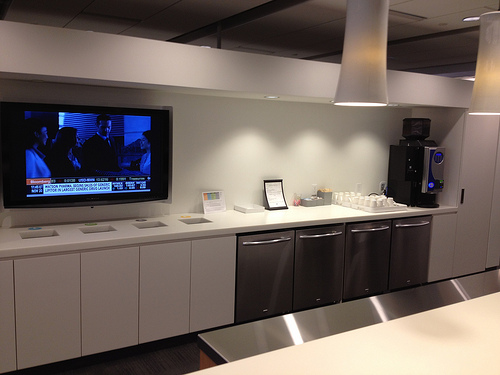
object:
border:
[0, 102, 173, 208]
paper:
[263, 180, 285, 207]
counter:
[13, 219, 83, 370]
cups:
[358, 197, 365, 207]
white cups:
[364, 199, 370, 206]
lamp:
[333, 0, 391, 115]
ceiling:
[388, 1, 499, 39]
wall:
[173, 107, 388, 203]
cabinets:
[5, 233, 235, 363]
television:
[4, 103, 173, 203]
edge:
[185, 312, 256, 367]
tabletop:
[251, 266, 498, 372]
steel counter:
[194, 265, 500, 375]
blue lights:
[433, 150, 445, 164]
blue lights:
[427, 179, 435, 190]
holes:
[76, 224, 118, 235]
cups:
[369, 200, 377, 208]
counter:
[190, 209, 238, 333]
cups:
[388, 198, 394, 207]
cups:
[377, 199, 383, 208]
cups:
[363, 198, 369, 206]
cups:
[353, 197, 359, 205]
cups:
[333, 192, 338, 200]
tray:
[330, 202, 407, 212]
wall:
[182, 118, 242, 163]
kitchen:
[183, 267, 500, 374]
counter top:
[197, 267, 499, 363]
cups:
[388, 196, 395, 207]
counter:
[390, 193, 456, 285]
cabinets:
[235, 214, 433, 324]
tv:
[3, 102, 172, 206]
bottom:
[5, 193, 170, 209]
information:
[22, 177, 152, 200]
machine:
[388, 114, 445, 209]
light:
[331, 0, 390, 109]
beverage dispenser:
[386, 117, 445, 208]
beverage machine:
[383, 117, 448, 207]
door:
[451, 113, 499, 279]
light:
[463, 10, 498, 120]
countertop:
[253, 205, 315, 223]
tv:
[5, 102, 176, 216]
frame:
[261, 178, 286, 211]